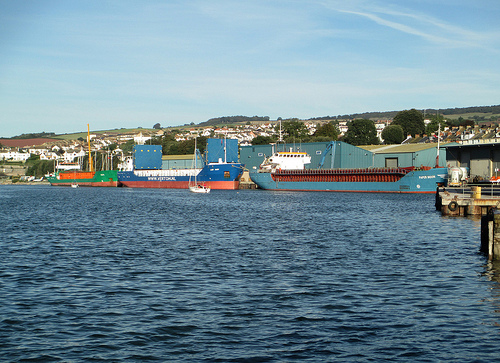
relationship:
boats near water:
[59, 153, 443, 191] [71, 206, 363, 326]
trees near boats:
[290, 102, 433, 150] [59, 153, 443, 191]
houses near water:
[24, 133, 141, 161] [71, 206, 363, 326]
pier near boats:
[435, 153, 499, 204] [59, 153, 443, 191]